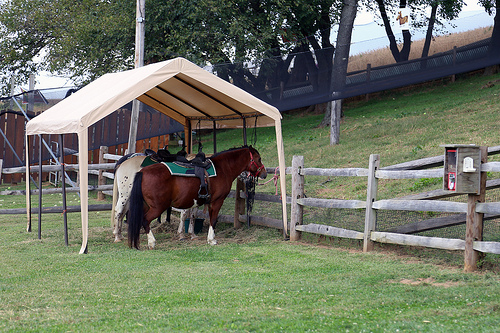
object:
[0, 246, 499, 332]
grass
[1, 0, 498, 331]
pasture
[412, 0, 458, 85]
trees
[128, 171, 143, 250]
tail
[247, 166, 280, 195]
rope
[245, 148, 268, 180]
red bridal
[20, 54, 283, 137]
roof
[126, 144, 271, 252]
horse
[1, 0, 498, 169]
mesh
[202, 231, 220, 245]
white feet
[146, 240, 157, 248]
white feet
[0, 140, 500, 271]
fence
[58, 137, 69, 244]
pole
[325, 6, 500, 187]
hill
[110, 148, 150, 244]
horse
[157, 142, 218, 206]
horse saddle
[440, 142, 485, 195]
box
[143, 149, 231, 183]
back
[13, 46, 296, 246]
canopy